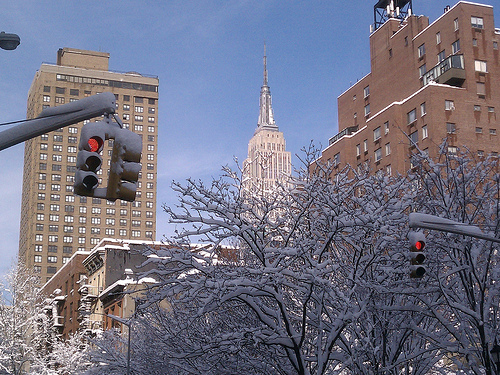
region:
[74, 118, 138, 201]
signal light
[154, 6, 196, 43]
white clouds in blue sky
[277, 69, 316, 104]
white clouds in blue sky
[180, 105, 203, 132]
white clouds in blue sky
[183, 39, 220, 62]
white clouds in blue sky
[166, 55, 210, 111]
white clouds in blue sky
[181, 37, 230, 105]
white clouds in blue sky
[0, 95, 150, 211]
black traffic light attached to pole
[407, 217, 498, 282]
black traffic light attached to pole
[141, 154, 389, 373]
huge tree covered in snow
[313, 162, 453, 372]
huge tree covered in snow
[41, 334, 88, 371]
huge tree covered in snow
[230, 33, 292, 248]
huge tan building in background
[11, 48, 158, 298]
huge light brown building in background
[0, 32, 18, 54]
tall street light pole in distance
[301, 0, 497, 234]
huge brown building with many windows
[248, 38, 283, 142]
TOP OF TOWER ON BUILDING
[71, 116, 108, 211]
HANGING TRAFFIC STREET SIGNAL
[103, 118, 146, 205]
HANGING TRAFFIC STREET SIGNAL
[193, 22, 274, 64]
CLEAR BLUE WINTER SKY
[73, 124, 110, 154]
RED LIIGHT OF TRAFFIC SIGNAL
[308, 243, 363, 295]
SNOW COVERED BRANCHES OF TREE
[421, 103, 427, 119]
glass window on building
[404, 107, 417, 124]
glass window on building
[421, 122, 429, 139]
glass window on building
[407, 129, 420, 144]
glass window on building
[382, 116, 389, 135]
glass window on building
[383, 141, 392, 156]
glass window on building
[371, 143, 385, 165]
glass window on building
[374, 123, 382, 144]
glass window on building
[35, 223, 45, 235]
glass window on building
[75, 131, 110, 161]
red light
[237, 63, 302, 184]
tower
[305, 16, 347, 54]
white clouds in blue sky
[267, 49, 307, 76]
white clouds in blue sky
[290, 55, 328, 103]
white clouds in blue sky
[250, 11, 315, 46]
white clouds in blue sky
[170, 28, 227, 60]
white clouds in blue sky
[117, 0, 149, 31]
white clouds in blue sky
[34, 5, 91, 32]
white clouds in blue sky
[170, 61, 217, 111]
white clouds in blue sky